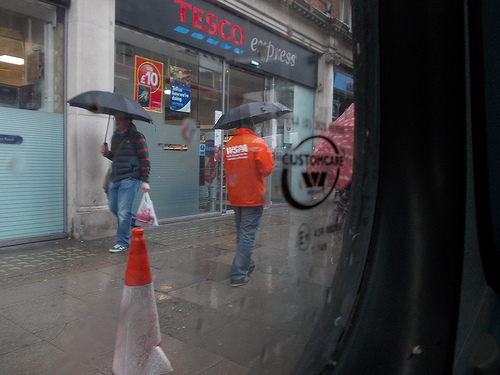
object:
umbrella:
[66, 90, 155, 125]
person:
[218, 121, 273, 287]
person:
[98, 112, 150, 254]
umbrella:
[213, 101, 293, 130]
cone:
[109, 226, 169, 375]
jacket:
[221, 127, 274, 208]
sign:
[134, 56, 164, 114]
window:
[198, 56, 223, 210]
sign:
[169, 65, 191, 113]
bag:
[134, 189, 159, 230]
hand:
[140, 180, 150, 194]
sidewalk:
[0, 204, 338, 375]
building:
[1, 0, 355, 249]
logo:
[224, 144, 251, 162]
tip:
[131, 228, 144, 236]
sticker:
[279, 135, 346, 212]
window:
[0, 0, 380, 374]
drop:
[324, 286, 335, 303]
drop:
[334, 314, 343, 325]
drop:
[356, 42, 361, 56]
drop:
[347, 252, 351, 265]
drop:
[199, 313, 208, 335]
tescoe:
[174, 0, 246, 47]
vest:
[110, 125, 141, 183]